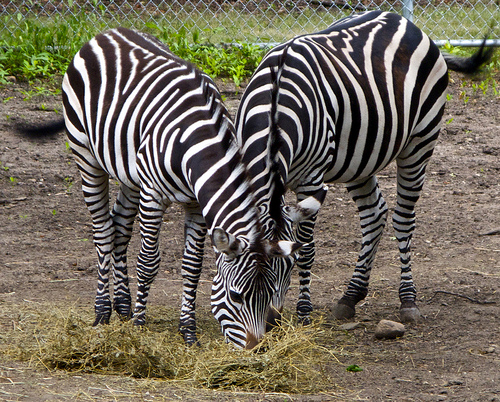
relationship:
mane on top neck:
[223, 122, 278, 190] [170, 91, 274, 278]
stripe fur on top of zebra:
[312, 37, 420, 141] [232, 8, 449, 322]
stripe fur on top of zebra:
[80, 61, 156, 147] [60, 22, 317, 354]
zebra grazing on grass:
[232, 8, 449, 322] [203, 343, 313, 399]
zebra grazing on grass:
[60, 22, 317, 354] [203, 343, 313, 399]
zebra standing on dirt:
[60, 22, 277, 359] [5, 59, 496, 397]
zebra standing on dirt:
[232, 8, 449, 322] [5, 59, 496, 397]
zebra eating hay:
[232, 8, 449, 322] [125, 329, 276, 379]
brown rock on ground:
[375, 319, 407, 340] [347, 332, 380, 358]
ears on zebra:
[211, 224, 303, 263] [52, 30, 437, 331]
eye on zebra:
[224, 283, 250, 306] [9, 23, 327, 361]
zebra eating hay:
[211, 8, 450, 342] [32, 307, 361, 393]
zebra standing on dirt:
[60, 22, 317, 354] [58, 272, 418, 393]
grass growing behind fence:
[0, 6, 499, 67] [214, 10, 266, 39]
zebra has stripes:
[60, 22, 277, 359] [181, 123, 196, 136]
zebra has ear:
[60, 22, 317, 354] [209, 232, 239, 254]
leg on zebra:
[133, 180, 163, 325] [60, 22, 317, 354]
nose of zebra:
[247, 329, 272, 354] [221, 11, 492, 330]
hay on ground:
[27, 297, 349, 389] [2, 39, 497, 399]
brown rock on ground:
[375, 319, 407, 340] [29, 271, 325, 400]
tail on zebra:
[9, 112, 64, 142] [9, 23, 327, 361]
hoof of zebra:
[326, 287, 364, 326] [61, 19, 468, 356]